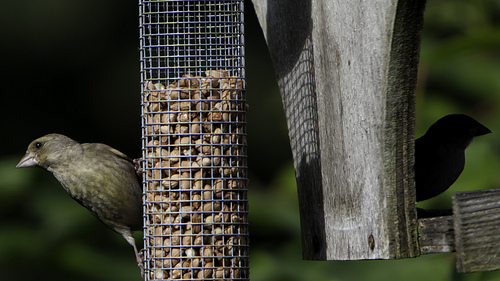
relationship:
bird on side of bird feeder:
[15, 131, 145, 275] [137, 1, 249, 279]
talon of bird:
[135, 251, 148, 276] [15, 131, 145, 275]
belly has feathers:
[87, 167, 127, 209] [92, 170, 121, 203]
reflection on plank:
[242, 3, 329, 261] [249, 2, 430, 262]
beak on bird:
[15, 151, 36, 168] [15, 131, 145, 275]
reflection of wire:
[242, 3, 329, 261] [137, 1, 252, 279]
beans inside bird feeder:
[141, 68, 246, 280] [137, 1, 249, 279]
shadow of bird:
[408, 109, 492, 204] [412, 113, 490, 203]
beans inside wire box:
[141, 68, 246, 280] [136, 0, 249, 279]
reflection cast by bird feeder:
[242, 3, 329, 261] [137, 1, 249, 279]